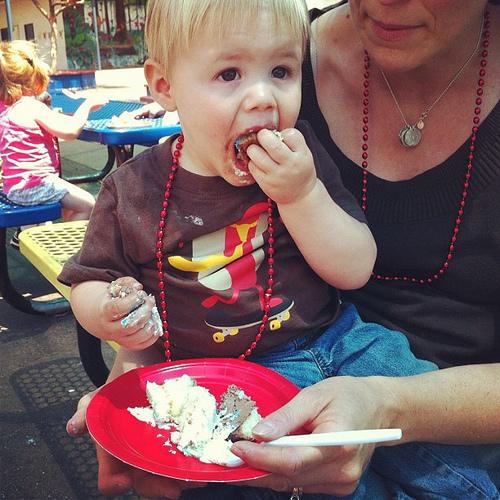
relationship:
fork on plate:
[259, 420, 411, 446] [70, 342, 321, 477]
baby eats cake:
[57, 0, 497, 499] [137, 367, 264, 460]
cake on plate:
[126, 369, 271, 471] [78, 350, 313, 490]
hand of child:
[244, 125, 318, 211] [56, 2, 497, 497]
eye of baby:
[270, 63, 290, 80] [57, 0, 497, 499]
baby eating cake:
[57, 0, 497, 499] [146, 366, 263, 457]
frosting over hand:
[90, 349, 263, 492] [239, 122, 318, 205]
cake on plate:
[126, 369, 271, 471] [77, 332, 352, 492]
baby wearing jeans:
[57, 0, 497, 499] [296, 345, 498, 499]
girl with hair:
[1, 39, 106, 246] [1, 39, 49, 105]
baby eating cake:
[57, 0, 497, 499] [128, 369, 270, 471]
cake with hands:
[128, 369, 270, 471] [245, 124, 322, 206]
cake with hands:
[128, 369, 270, 471] [96, 270, 163, 353]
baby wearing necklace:
[57, 0, 497, 499] [146, 123, 295, 374]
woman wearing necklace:
[66, 0, 499, 498] [337, 11, 495, 296]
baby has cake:
[57, 0, 497, 499] [126, 369, 271, 471]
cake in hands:
[126, 369, 271, 471] [97, 279, 162, 349]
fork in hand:
[199, 426, 403, 472] [224, 374, 401, 498]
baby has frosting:
[57, 0, 497, 499] [125, 372, 264, 465]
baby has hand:
[57, 0, 497, 499] [239, 122, 318, 205]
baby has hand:
[57, 0, 497, 499] [96, 275, 165, 352]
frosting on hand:
[125, 372, 264, 465] [239, 122, 318, 205]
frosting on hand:
[125, 372, 264, 465] [96, 275, 165, 352]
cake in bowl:
[126, 369, 271, 471] [84, 356, 308, 483]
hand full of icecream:
[244, 129, 321, 210] [127, 368, 284, 467]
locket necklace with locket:
[375, 17, 490, 149] [394, 123, 419, 151]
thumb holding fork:
[192, 376, 322, 453] [199, 426, 403, 472]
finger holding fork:
[227, 430, 356, 473] [199, 426, 403, 472]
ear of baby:
[137, 57, 177, 122] [57, 0, 497, 499]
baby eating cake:
[57, 0, 499, 497] [233, 120, 285, 181]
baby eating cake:
[57, 0, 499, 497] [235, 128, 270, 166]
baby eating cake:
[57, 0, 499, 497] [142, 372, 270, 452]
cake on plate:
[126, 369, 271, 471] [78, 342, 493, 401]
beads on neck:
[357, 1, 492, 283] [393, 18, 478, 88]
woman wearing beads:
[66, 0, 499, 498] [357, 1, 492, 283]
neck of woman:
[393, 18, 478, 88] [66, 0, 499, 498]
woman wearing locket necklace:
[85, 9, 482, 497] [375, 15, 487, 149]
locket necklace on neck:
[375, 15, 487, 149] [361, 20, 480, 90]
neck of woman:
[361, 20, 480, 90] [85, 9, 482, 497]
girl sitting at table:
[0, 40, 110, 248] [7, 73, 195, 235]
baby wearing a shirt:
[57, 0, 497, 499] [77, 123, 370, 369]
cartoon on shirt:
[169, 195, 293, 341] [77, 123, 370, 369]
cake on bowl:
[126, 369, 271, 471] [84, 356, 308, 483]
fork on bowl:
[199, 426, 403, 472] [84, 356, 308, 483]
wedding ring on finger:
[280, 481, 315, 498] [259, 479, 353, 496]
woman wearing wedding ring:
[85, 9, 482, 497] [280, 481, 315, 498]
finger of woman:
[259, 479, 353, 496] [85, 9, 482, 497]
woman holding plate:
[66, 0, 499, 498] [118, 353, 300, 484]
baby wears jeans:
[57, 0, 497, 499] [357, 330, 389, 354]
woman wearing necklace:
[66, 0, 499, 498] [359, 7, 492, 287]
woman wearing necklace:
[66, 0, 499, 498] [154, 134, 275, 363]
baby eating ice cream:
[57, 0, 497, 499] [139, 350, 237, 442]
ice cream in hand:
[139, 350, 237, 442] [239, 122, 318, 205]